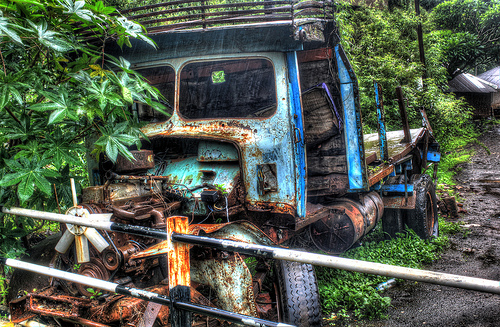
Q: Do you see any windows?
A: Yes, there is a window.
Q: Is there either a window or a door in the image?
A: Yes, there is a window.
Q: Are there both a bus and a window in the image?
A: No, there is a window but no buses.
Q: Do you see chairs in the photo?
A: No, there are no chairs.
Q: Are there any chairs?
A: No, there are no chairs.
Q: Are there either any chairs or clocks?
A: No, there are no chairs or clocks.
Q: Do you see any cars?
A: No, there are no cars.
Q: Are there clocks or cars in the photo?
A: No, there are no cars or clocks.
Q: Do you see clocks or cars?
A: No, there are no cars or clocks.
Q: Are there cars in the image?
A: No, there are no cars.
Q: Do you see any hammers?
A: No, there are no hammers.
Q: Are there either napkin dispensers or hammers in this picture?
A: No, there are no hammers or napkin dispensers.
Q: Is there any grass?
A: Yes, there is grass.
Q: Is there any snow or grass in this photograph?
A: Yes, there is grass.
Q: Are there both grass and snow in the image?
A: No, there is grass but no snow.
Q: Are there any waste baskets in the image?
A: No, there are no waste baskets.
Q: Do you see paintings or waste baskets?
A: No, there are no waste baskets or paintings.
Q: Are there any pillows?
A: No, there are no pillows.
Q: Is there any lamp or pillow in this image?
A: No, there are no pillows or lamps.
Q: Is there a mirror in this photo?
A: No, there are no mirrors.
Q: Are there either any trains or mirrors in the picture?
A: No, there are no mirrors or trains.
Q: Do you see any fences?
A: Yes, there is a fence.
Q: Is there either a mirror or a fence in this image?
A: Yes, there is a fence.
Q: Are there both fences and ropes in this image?
A: No, there is a fence but no ropes.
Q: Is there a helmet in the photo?
A: No, there are no helmets.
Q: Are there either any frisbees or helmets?
A: No, there are no helmets or frisbees.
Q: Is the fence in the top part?
A: Yes, the fence is in the top of the image.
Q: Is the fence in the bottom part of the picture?
A: No, the fence is in the top of the image.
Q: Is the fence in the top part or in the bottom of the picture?
A: The fence is in the top of the image.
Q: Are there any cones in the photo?
A: No, there are no cones.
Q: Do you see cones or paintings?
A: No, there are no cones or paintings.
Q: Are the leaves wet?
A: Yes, the leaves are wet.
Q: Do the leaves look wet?
A: Yes, the leaves are wet.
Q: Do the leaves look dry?
A: No, the leaves are wet.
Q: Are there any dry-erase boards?
A: No, there are no dry-erase boards.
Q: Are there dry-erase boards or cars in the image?
A: No, there are no dry-erase boards or cars.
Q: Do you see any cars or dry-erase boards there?
A: No, there are no dry-erase boards or cars.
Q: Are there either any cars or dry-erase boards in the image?
A: No, there are no dry-erase boards or cars.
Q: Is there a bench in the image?
A: No, there are no benches.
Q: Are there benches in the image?
A: No, there are no benches.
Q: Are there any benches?
A: No, there are no benches.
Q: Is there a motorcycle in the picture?
A: No, there are no motorcycles.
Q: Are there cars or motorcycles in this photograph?
A: No, there are no motorcycles or cars.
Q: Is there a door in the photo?
A: Yes, there is a door.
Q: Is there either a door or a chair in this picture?
A: Yes, there is a door.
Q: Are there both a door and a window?
A: Yes, there are both a door and a window.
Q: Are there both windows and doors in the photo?
A: Yes, there are both a door and a window.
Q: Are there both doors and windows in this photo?
A: Yes, there are both a door and a window.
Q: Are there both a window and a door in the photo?
A: Yes, there are both a door and a window.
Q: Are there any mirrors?
A: No, there are no mirrors.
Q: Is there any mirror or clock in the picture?
A: No, there are no mirrors or clocks.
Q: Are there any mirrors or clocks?
A: No, there are no mirrors or clocks.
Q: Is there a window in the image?
A: Yes, there is a window.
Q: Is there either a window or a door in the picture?
A: Yes, there is a window.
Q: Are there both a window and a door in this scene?
A: Yes, there are both a window and a door.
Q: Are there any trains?
A: No, there are no trains.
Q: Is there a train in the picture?
A: No, there are no trains.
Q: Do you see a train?
A: No, there are no trains.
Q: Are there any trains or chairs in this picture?
A: No, there are no trains or chairs.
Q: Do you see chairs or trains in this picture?
A: No, there are no trains or chairs.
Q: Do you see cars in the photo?
A: No, there are no cars.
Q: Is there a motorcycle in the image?
A: No, there are no motorcycles.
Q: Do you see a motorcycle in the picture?
A: No, there are no motorcycles.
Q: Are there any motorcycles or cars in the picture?
A: No, there are no motorcycles or cars.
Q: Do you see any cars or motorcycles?
A: No, there are no motorcycles or cars.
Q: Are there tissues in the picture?
A: No, there are no tissues.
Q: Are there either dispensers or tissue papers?
A: No, there are no tissue papers or dispensers.